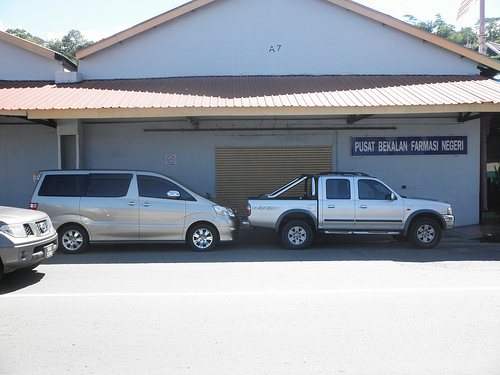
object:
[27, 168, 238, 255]
car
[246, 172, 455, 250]
truck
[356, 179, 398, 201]
window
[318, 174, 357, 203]
window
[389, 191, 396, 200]
mirror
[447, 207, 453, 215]
light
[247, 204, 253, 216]
light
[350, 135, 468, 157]
sign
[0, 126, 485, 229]
wall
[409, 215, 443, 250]
tire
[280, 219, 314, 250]
tire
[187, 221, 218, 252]
tire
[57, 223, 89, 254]
tire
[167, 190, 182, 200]
mirror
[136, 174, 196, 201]
window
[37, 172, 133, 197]
window